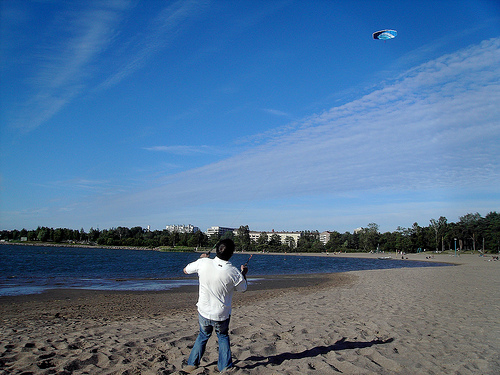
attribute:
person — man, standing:
[183, 237, 252, 375]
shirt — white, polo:
[184, 255, 248, 323]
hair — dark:
[215, 238, 235, 264]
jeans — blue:
[186, 310, 235, 369]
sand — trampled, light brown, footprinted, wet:
[0, 251, 499, 374]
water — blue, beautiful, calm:
[1, 241, 457, 288]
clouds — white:
[131, 38, 500, 206]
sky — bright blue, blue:
[0, 1, 500, 236]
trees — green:
[0, 209, 500, 255]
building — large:
[200, 224, 325, 255]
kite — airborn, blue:
[372, 26, 398, 45]